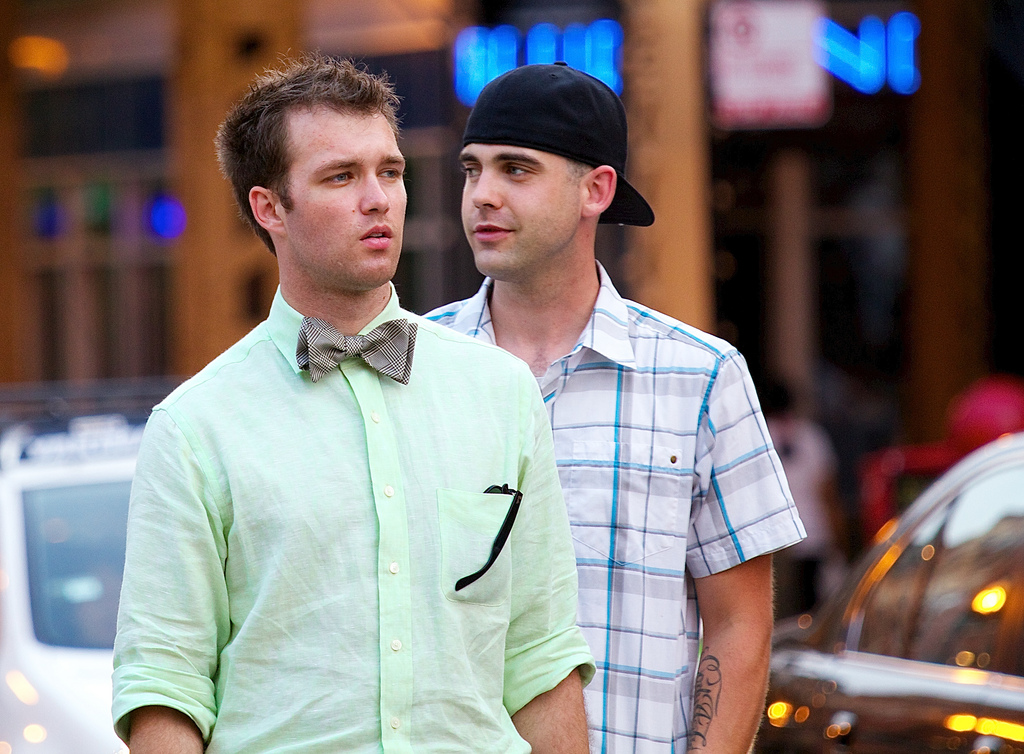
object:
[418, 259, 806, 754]
shirt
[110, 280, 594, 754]
shirt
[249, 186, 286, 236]
ear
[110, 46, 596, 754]
guy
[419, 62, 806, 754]
guy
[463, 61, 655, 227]
cap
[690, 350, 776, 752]
arm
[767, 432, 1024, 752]
lights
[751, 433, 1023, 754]
car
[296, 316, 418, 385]
bow tie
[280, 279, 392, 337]
neck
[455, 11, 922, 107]
neon lights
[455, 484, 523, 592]
glasses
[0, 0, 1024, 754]
city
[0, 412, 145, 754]
car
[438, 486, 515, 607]
pocket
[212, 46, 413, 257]
hair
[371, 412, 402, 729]
buttons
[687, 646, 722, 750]
tattoo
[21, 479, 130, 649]
windshield